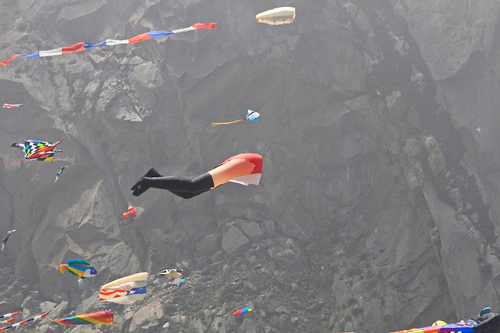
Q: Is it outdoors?
A: Yes, it is outdoors.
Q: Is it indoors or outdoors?
A: It is outdoors.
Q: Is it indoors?
A: No, it is outdoors.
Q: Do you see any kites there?
A: Yes, there is a kite.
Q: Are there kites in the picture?
A: Yes, there is a kite.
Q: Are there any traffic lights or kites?
A: Yes, there is a kite.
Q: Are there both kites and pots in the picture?
A: No, there is a kite but no pots.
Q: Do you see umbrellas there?
A: No, there are no umbrellas.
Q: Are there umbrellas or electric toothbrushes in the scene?
A: No, there are no umbrellas or electric toothbrushes.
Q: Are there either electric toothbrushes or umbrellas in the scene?
A: No, there are no umbrellas or electric toothbrushes.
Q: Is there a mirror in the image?
A: No, there are no mirrors.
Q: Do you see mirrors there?
A: No, there are no mirrors.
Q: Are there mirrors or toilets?
A: No, there are no mirrors or toilets.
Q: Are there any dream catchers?
A: No, there are no dream catchers.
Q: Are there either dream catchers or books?
A: No, there are no dream catchers or books.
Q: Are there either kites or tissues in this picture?
A: Yes, there is a kite.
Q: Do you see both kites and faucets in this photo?
A: No, there is a kite but no faucets.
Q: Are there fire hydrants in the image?
A: No, there are no fire hydrants.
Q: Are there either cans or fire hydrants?
A: No, there are no fire hydrants or cans.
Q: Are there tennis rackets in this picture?
A: No, there are no tennis rackets.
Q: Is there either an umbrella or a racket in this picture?
A: No, there are no rackets or umbrellas.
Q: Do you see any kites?
A: Yes, there is a kite.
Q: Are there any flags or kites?
A: Yes, there is a kite.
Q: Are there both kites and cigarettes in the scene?
A: No, there is a kite but no cigarettes.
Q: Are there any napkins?
A: No, there are no napkins.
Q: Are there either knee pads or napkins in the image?
A: No, there are no napkins or knee pads.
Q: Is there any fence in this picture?
A: No, there are no fences.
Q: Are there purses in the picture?
A: No, there are no purses.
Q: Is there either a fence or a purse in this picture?
A: No, there are no purses or fences.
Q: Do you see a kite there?
A: Yes, there is a kite.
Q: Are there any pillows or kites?
A: Yes, there is a kite.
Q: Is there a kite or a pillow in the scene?
A: Yes, there is a kite.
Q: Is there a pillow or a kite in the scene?
A: Yes, there is a kite.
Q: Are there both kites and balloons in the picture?
A: No, there is a kite but no balloons.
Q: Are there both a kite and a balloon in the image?
A: No, there is a kite but no balloons.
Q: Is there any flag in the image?
A: No, there are no flags.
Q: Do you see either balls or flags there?
A: No, there are no flags or balls.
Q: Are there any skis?
A: No, there are no skis.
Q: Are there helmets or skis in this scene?
A: No, there are no skis or helmets.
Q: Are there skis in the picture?
A: No, there are no skis.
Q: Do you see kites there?
A: Yes, there is a kite.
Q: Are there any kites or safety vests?
A: Yes, there is a kite.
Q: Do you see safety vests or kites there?
A: Yes, there is a kite.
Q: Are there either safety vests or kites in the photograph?
A: Yes, there is a kite.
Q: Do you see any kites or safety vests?
A: Yes, there is a kite.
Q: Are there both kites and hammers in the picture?
A: No, there is a kite but no hammers.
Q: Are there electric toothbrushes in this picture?
A: No, there are no electric toothbrushes.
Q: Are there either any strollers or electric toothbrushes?
A: No, there are no electric toothbrushes or strollers.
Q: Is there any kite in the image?
A: Yes, there is a kite.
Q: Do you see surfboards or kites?
A: Yes, there is a kite.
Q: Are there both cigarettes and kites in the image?
A: No, there is a kite but no cigarettes.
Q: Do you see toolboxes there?
A: No, there are no toolboxes.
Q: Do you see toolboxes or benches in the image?
A: No, there are no toolboxes or benches.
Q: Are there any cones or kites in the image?
A: Yes, there is a kite.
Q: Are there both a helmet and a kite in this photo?
A: No, there is a kite but no helmets.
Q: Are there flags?
A: No, there are no flags.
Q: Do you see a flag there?
A: No, there are no flags.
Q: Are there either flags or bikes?
A: No, there are no flags or bikes.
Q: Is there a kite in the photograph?
A: Yes, there is a kite.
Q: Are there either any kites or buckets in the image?
A: Yes, there is a kite.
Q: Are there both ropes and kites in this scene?
A: No, there is a kite but no ropes.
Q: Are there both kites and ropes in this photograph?
A: No, there is a kite but no ropes.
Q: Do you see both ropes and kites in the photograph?
A: No, there is a kite but no ropes.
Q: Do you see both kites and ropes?
A: No, there is a kite but no ropes.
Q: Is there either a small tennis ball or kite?
A: Yes, there is a small kite.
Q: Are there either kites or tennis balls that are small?
A: Yes, the kite is small.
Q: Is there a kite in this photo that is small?
A: Yes, there is a small kite.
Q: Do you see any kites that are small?
A: Yes, there is a kite that is small.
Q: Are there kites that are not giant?
A: Yes, there is a small kite.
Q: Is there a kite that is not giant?
A: Yes, there is a small kite.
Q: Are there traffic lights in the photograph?
A: No, there are no traffic lights.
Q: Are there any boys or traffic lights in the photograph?
A: No, there are no traffic lights or boys.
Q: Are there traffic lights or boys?
A: No, there are no traffic lights or boys.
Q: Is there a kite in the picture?
A: Yes, there is a kite.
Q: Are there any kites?
A: Yes, there is a kite.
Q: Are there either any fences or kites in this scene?
A: Yes, there is a kite.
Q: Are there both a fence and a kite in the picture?
A: No, there is a kite but no fences.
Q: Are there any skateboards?
A: No, there are no skateboards.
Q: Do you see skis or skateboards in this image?
A: No, there are no skateboards or skis.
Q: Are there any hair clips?
A: No, there are no hair clips.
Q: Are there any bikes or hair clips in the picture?
A: No, there are no hair clips or bikes.